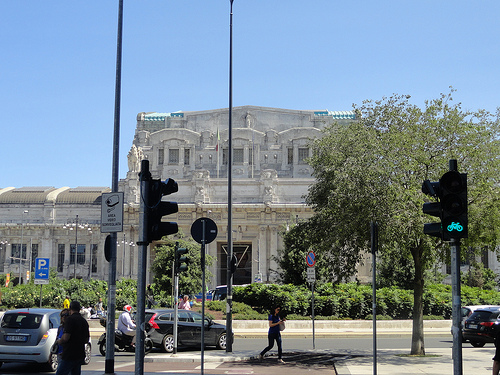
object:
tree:
[286, 87, 497, 371]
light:
[420, 159, 468, 241]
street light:
[139, 160, 178, 245]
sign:
[370, 221, 378, 255]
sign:
[306, 250, 316, 267]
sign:
[306, 268, 316, 282]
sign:
[34, 258, 50, 284]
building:
[0, 104, 497, 287]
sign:
[101, 191, 123, 233]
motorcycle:
[97, 321, 153, 356]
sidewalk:
[119, 347, 499, 374]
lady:
[259, 305, 287, 366]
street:
[51, 328, 499, 352]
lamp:
[421, 160, 468, 375]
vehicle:
[462, 306, 499, 347]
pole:
[451, 239, 462, 373]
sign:
[190, 217, 218, 244]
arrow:
[38, 272, 46, 276]